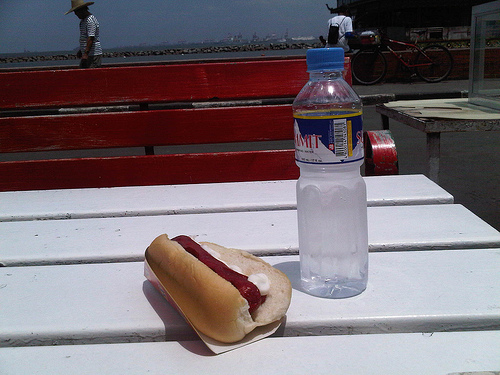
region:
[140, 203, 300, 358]
Hot dog with ketchup.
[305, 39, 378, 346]
Bottle of bottled water.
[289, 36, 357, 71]
Blue cap on a bottle of water.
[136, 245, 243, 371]
Part of a hot dog bun.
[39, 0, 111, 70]
Man with a cowboy hat.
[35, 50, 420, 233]
Metal bench painted red.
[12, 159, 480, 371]
White painted picnic table.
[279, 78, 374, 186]
Label on a water bottle.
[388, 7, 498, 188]
White chair with peeling paint.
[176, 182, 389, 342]
Hot dog and water on table.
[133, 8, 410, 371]
hot dog and water on a white table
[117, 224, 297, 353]
hot dog on a bun in a disposable paper container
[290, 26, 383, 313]
bottle of cold water with a blue cap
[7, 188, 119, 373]
white slatted picnic table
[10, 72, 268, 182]
red wood bench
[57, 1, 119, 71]
man in a sombrero walking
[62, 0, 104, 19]
sombrero on the man's head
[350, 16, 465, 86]
red bicycle leaning against a low wall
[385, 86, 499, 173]
rough outdoor table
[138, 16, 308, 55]
seawall in the background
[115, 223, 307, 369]
hot dog in a bun on a napkin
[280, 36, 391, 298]
clear water bottle with blue lid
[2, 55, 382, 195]
red metal and wood bench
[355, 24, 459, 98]
red and black bike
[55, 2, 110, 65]
adult man with straw hat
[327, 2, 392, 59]
man with black backpack standing on street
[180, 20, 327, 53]
shipping out in water at a distance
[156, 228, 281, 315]
hot dog with mayo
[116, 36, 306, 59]
rock wall dividing two bodies of water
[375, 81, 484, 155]
cement and asphalt sidewalk and street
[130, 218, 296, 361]
hot dog sitting on the table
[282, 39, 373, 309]
water bottle next to the hot dog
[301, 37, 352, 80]
blue cap on a water bottle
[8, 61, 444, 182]
red bench next to the table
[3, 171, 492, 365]
wooden table painted white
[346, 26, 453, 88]
red bike resting on a wall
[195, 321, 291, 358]
paper product under the hot dog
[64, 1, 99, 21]
large brown hat on the mans head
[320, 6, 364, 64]
man wearing a white shirt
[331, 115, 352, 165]
bar code on the side of the bottle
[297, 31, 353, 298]
blue cap on water bottle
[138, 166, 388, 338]
hot dog next to water bottle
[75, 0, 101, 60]
man wearing a hat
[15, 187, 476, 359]
gray wooden slat table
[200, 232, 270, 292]
onions in the hot dog bun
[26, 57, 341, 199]
dark red wooden bench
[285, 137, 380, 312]
water in the water bottle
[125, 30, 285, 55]
water behind the red bench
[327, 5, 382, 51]
man carrying a backpack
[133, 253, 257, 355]
hot dog sitting in paper holder